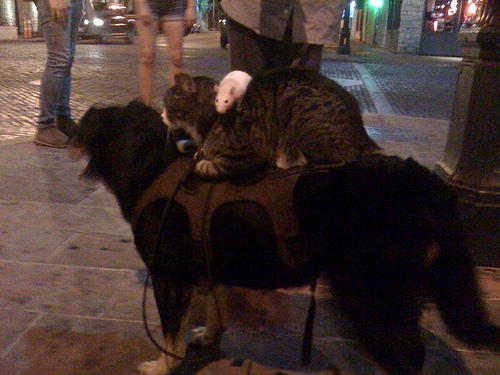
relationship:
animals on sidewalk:
[102, 66, 473, 320] [32, 269, 324, 374]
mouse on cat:
[215, 70, 253, 113] [161, 82, 368, 172]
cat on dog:
[161, 82, 368, 172] [98, 128, 471, 309]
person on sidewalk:
[23, 9, 101, 170] [32, 269, 324, 374]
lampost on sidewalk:
[422, 10, 499, 204] [32, 269, 324, 374]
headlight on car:
[80, 15, 104, 28] [80, 4, 140, 40]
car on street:
[80, 4, 140, 40] [56, 35, 115, 89]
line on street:
[346, 57, 391, 118] [56, 35, 115, 89]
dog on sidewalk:
[98, 128, 471, 309] [32, 269, 324, 374]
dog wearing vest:
[98, 128, 471, 309] [156, 179, 310, 247]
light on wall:
[366, 3, 389, 17] [363, 15, 391, 45]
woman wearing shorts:
[134, 3, 191, 99] [131, 2, 190, 23]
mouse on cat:
[208, 69, 252, 115] [161, 82, 368, 172]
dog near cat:
[98, 128, 471, 309] [161, 82, 368, 172]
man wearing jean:
[33, 3, 83, 151] [34, 27, 67, 119]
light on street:
[366, 3, 389, 17] [56, 35, 115, 89]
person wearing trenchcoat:
[219, 4, 333, 63] [221, 10, 350, 50]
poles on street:
[336, 6, 350, 59] [56, 35, 115, 89]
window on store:
[430, 11, 465, 34] [400, 4, 480, 63]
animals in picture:
[102, 66, 473, 320] [25, 10, 489, 318]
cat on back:
[161, 82, 368, 172] [160, 167, 375, 190]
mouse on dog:
[215, 70, 253, 113] [98, 128, 471, 309]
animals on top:
[102, 66, 473, 320] [148, 30, 424, 85]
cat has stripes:
[161, 82, 368, 172] [299, 96, 328, 128]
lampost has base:
[422, 10, 499, 183] [432, 66, 498, 188]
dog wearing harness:
[98, 128, 471, 309] [156, 179, 310, 247]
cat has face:
[161, 82, 368, 172] [154, 90, 180, 134]